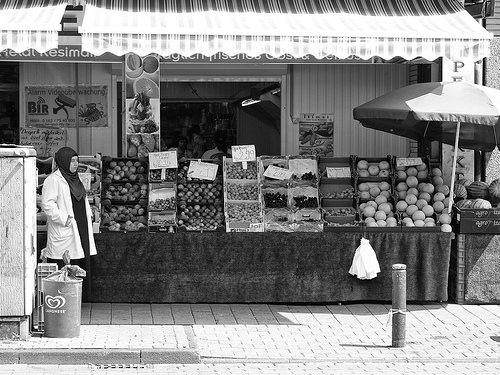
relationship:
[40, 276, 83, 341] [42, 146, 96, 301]
trash by lady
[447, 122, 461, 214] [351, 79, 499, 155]
pole on umbrella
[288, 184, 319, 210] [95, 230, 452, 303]
fruit on shelf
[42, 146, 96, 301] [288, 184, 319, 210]
lady by fruit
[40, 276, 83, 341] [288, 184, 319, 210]
trash by fruit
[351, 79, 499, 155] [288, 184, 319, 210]
umbrella by fruit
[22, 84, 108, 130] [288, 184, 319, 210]
sign by fruit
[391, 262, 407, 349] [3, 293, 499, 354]
post on sidewalk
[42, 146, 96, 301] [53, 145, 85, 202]
lady with scarf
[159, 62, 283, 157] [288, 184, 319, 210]
window behind fruit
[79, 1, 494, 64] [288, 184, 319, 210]
awning above fruit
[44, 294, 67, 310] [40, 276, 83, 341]
heart on trash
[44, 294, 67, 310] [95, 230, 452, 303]
heart on shelf